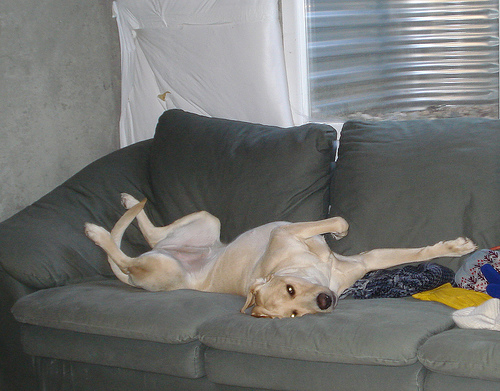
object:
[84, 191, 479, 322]
dog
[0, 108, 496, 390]
couch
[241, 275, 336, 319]
head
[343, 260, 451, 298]
objects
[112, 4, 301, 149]
sheet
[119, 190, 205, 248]
legs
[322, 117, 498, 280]
pillow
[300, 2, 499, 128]
blinds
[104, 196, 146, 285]
tail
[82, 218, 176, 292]
legs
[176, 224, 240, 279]
belly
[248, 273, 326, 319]
face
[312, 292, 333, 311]
nose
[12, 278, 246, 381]
cushion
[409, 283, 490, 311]
glove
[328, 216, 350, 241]
paw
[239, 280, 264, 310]
ear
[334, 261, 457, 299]
blanket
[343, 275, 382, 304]
fringe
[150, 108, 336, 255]
pillows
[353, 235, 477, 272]
front legs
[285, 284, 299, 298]
eyes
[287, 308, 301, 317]
eyeballs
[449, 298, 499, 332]
object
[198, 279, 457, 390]
cushions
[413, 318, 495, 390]
cushions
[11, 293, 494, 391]
edge